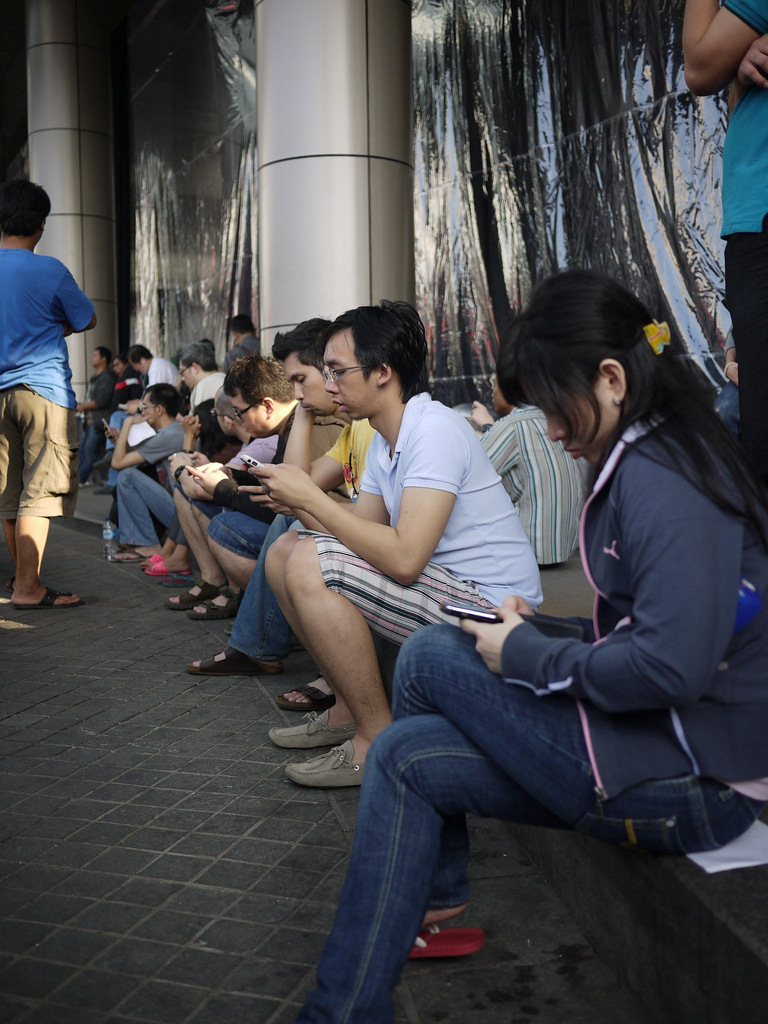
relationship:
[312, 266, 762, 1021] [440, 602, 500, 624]
woman holding cellphone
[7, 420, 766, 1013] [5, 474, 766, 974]
tiles on ground